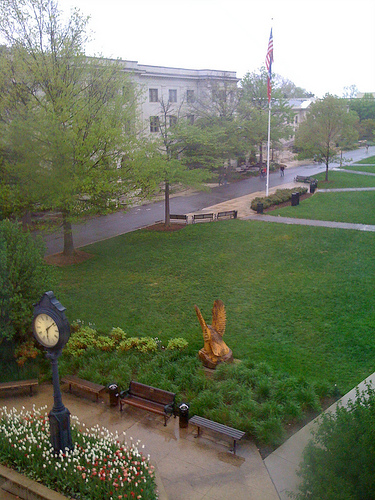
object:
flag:
[265, 24, 273, 102]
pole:
[266, 109, 271, 197]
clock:
[31, 290, 73, 452]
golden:
[195, 300, 234, 369]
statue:
[195, 298, 232, 370]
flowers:
[108, 447, 111, 451]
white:
[88, 450, 95, 459]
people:
[281, 164, 285, 176]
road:
[46, 141, 375, 258]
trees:
[0, 0, 141, 256]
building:
[0, 53, 238, 170]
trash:
[179, 403, 188, 428]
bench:
[119, 382, 176, 426]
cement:
[159, 450, 226, 498]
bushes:
[251, 187, 307, 210]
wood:
[64, 225, 73, 254]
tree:
[130, 104, 215, 229]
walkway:
[243, 214, 373, 231]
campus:
[0, 0, 375, 499]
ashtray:
[109, 383, 118, 403]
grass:
[26, 210, 374, 462]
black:
[52, 364, 61, 402]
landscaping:
[14, 341, 38, 367]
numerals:
[45, 316, 48, 320]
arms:
[165, 401, 175, 409]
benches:
[188, 416, 245, 447]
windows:
[149, 89, 158, 102]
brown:
[122, 396, 165, 416]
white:
[35, 314, 60, 346]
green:
[94, 116, 109, 137]